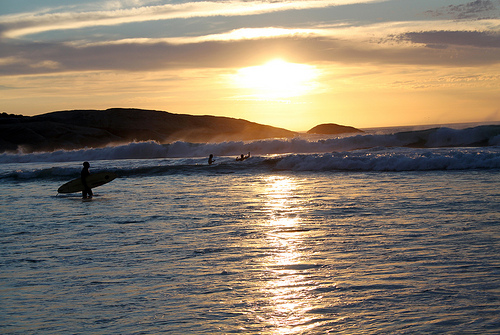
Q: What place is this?
A: It is an ocean.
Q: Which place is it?
A: It is an ocean.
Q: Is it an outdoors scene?
A: Yes, it is outdoors.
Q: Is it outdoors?
A: Yes, it is outdoors.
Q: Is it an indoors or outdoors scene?
A: It is outdoors.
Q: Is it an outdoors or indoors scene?
A: It is outdoors.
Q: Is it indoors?
A: No, it is outdoors.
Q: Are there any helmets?
A: No, there are no helmets.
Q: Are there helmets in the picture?
A: No, there are no helmets.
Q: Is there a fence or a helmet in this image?
A: No, there are no helmets or fences.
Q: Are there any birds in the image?
A: No, there are no birds.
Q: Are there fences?
A: No, there are no fences.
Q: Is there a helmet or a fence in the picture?
A: No, there are no fences or helmets.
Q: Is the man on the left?
A: Yes, the man is on the left of the image.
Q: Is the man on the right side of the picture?
A: No, the man is on the left of the image.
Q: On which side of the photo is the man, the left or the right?
A: The man is on the left of the image.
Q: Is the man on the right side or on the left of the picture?
A: The man is on the left of the image.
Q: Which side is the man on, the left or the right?
A: The man is on the left of the image.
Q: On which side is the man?
A: The man is on the left of the image.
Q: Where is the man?
A: The man is in the ocean.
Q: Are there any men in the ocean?
A: Yes, there is a man in the ocean.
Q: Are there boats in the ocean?
A: No, there is a man in the ocean.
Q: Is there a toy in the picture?
A: No, there are no toys.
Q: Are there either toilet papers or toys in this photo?
A: No, there are no toys or toilet papers.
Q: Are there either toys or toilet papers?
A: No, there are no toys or toilet papers.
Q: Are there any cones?
A: No, there are no cones.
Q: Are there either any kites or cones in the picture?
A: No, there are no cones or kites.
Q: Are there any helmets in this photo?
A: No, there are no helmets.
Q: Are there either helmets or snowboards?
A: No, there are no helmets or snowboards.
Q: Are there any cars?
A: No, there are no cars.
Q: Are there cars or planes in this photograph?
A: No, there are no cars or planes.